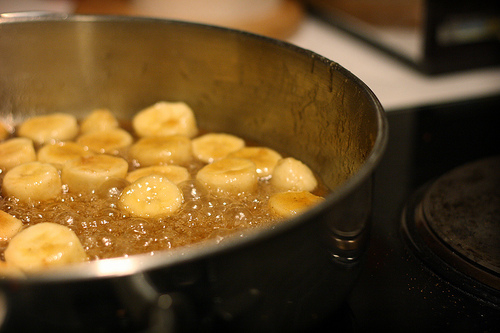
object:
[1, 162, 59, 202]
banana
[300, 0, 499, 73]
appliance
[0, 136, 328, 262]
liquid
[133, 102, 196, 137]
banana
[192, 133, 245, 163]
slice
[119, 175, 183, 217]
banana slice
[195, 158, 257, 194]
banana slice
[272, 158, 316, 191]
banana slice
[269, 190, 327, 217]
banana slice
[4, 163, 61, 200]
slice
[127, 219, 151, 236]
bubbles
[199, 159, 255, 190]
banana slice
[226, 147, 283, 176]
banana slice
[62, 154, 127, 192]
banana slice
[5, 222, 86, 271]
banana slice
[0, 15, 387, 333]
pan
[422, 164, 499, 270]
stove